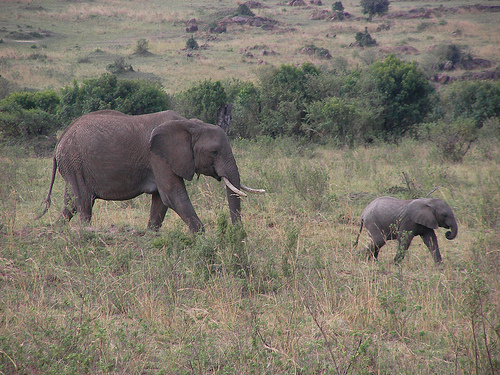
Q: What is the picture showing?
A: It is showing a field.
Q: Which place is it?
A: It is a field.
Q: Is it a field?
A: Yes, it is a field.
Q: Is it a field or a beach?
A: It is a field.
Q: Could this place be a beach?
A: No, it is a field.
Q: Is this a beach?
A: No, it is a field.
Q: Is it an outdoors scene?
A: Yes, it is outdoors.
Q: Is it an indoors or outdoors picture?
A: It is outdoors.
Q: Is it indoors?
A: No, it is outdoors.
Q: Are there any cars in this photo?
A: No, there are no cars.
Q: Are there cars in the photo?
A: No, there are no cars.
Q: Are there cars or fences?
A: No, there are no cars or fences.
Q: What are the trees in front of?
A: The trees are in front of the field.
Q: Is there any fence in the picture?
A: No, there are no fences.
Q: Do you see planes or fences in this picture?
A: No, there are no fences or planes.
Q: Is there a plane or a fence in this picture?
A: No, there are no fences or airplanes.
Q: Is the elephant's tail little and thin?
A: Yes, the tail is little and thin.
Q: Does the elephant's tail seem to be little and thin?
A: Yes, the tail is little and thin.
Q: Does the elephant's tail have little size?
A: Yes, the tail is little.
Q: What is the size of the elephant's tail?
A: The tail is little.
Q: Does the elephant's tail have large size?
A: No, the tail is little.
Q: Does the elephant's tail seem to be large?
A: No, the tail is little.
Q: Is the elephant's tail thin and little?
A: Yes, the tail is thin and little.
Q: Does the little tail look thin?
A: Yes, the tail is thin.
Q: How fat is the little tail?
A: The tail is thin.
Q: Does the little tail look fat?
A: No, the tail is thin.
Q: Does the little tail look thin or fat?
A: The tail is thin.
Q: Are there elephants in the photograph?
A: Yes, there is an elephant.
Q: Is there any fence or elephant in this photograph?
A: Yes, there is an elephant.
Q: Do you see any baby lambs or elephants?
A: Yes, there is a baby elephant.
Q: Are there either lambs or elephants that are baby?
A: Yes, the elephant is a baby.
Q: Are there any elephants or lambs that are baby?
A: Yes, the elephant is a baby.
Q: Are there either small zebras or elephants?
A: Yes, there is a small elephant.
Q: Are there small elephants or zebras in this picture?
A: Yes, there is a small elephant.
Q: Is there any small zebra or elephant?
A: Yes, there is a small elephant.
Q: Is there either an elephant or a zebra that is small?
A: Yes, the elephant is small.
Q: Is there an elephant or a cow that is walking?
A: Yes, the elephant is walking.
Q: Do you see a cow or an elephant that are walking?
A: Yes, the elephant is walking.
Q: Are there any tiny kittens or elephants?
A: Yes, there is a tiny elephant.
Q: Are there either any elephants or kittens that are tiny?
A: Yes, the elephant is tiny.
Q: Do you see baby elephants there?
A: Yes, there is a baby elephant.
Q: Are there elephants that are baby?
A: Yes, there is an elephant that is a baby.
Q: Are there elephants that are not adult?
A: Yes, there is an baby elephant.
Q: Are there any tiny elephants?
A: Yes, there is a tiny elephant.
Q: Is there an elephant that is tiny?
A: Yes, there is an elephant that is tiny.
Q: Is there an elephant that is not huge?
A: Yes, there is a tiny elephant.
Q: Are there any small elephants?
A: Yes, there is a small elephant.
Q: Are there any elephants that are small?
A: Yes, there is an elephant that is small.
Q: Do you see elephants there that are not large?
A: Yes, there is a small elephant.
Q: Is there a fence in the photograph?
A: No, there are no fences.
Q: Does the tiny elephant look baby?
A: Yes, the elephant is a baby.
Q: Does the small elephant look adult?
A: No, the elephant is a baby.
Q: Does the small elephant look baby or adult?
A: The elephant is a baby.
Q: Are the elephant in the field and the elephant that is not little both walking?
A: Yes, both the elephant and the elephant are walking.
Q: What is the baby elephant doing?
A: The elephant is walking.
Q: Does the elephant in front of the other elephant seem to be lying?
A: No, the elephant is walking.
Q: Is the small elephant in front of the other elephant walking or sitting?
A: The elephant is walking.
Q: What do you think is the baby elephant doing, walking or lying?
A: The elephant is walking.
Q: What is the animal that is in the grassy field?
A: The animal is an elephant.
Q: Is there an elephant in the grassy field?
A: Yes, there is an elephant in the field.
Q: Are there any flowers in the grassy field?
A: No, there is an elephant in the field.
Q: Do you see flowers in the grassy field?
A: No, there is an elephant in the field.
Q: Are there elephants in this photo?
A: Yes, there is an elephant.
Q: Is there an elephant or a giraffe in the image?
A: Yes, there is an elephant.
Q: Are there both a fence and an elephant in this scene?
A: No, there is an elephant but no fences.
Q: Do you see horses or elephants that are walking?
A: Yes, the elephant is walking.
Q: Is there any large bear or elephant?
A: Yes, there is a large elephant.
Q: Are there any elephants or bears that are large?
A: Yes, the elephant is large.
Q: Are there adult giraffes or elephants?
A: Yes, there is an adult elephant.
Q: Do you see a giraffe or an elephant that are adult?
A: Yes, the elephant is adult.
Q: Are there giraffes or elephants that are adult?
A: Yes, the elephant is adult.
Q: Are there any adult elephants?
A: Yes, there is an adult elephant.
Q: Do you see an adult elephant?
A: Yes, there is an adult elephant.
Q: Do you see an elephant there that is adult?
A: Yes, there is an elephant that is adult.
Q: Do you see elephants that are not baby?
A: Yes, there is a adult elephant.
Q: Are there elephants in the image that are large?
A: Yes, there is a large elephant.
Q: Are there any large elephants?
A: Yes, there is a large elephant.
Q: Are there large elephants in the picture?
A: Yes, there is a large elephant.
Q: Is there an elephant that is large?
A: Yes, there is an elephant that is large.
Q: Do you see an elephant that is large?
A: Yes, there is an elephant that is large.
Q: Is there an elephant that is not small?
A: Yes, there is a large elephant.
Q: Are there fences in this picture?
A: No, there are no fences.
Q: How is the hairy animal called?
A: The animal is an elephant.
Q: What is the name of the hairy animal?
A: The animal is an elephant.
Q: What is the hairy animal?
A: The animal is an elephant.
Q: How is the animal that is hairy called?
A: The animal is an elephant.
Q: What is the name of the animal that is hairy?
A: The animal is an elephant.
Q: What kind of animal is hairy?
A: The animal is an elephant.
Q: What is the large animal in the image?
A: The animal is an elephant.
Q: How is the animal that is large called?
A: The animal is an elephant.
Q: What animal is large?
A: The animal is an elephant.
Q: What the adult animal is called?
A: The animal is an elephant.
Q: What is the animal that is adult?
A: The animal is an elephant.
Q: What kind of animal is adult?
A: The animal is an elephant.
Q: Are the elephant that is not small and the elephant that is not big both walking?
A: Yes, both the elephant and the elephant are walking.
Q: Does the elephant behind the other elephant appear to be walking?
A: Yes, the elephant is walking.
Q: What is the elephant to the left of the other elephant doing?
A: The elephant is walking.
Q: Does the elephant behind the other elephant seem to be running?
A: No, the elephant is walking.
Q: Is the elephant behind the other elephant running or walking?
A: The elephant is walking.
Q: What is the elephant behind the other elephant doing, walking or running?
A: The elephant is walking.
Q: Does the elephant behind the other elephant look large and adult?
A: Yes, the elephant is large and adult.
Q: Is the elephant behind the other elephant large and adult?
A: Yes, the elephant is large and adult.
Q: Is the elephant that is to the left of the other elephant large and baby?
A: No, the elephant is large but adult.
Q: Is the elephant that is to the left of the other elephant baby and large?
A: No, the elephant is large but adult.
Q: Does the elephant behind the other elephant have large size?
A: Yes, the elephant is large.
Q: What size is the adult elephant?
A: The elephant is large.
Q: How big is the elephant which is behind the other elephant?
A: The elephant is large.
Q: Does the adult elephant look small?
A: No, the elephant is large.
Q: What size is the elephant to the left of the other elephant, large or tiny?
A: The elephant is large.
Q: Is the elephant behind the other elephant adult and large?
A: Yes, the elephant is adult and large.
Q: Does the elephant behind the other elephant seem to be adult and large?
A: Yes, the elephant is adult and large.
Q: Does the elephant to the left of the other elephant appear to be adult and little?
A: No, the elephant is adult but large.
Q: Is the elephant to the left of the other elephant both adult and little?
A: No, the elephant is adult but large.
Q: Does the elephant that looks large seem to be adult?
A: Yes, the elephant is adult.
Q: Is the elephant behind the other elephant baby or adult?
A: The elephant is adult.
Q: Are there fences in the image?
A: No, there are no fences.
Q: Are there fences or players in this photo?
A: No, there are no fences or players.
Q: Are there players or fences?
A: No, there are no fences or players.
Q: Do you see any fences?
A: No, there are no fences.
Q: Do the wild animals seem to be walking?
A: Yes, the animals are walking.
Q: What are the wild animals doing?
A: The animals are walking.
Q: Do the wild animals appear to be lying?
A: No, the animals are walking.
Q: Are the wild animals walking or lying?
A: The animals are walking.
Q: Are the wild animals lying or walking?
A: The animals are walking.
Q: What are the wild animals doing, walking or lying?
A: The animals are walking.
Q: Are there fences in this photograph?
A: No, there are no fences.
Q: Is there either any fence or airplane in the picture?
A: No, there are no fences or airplanes.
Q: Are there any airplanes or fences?
A: No, there are no fences or airplanes.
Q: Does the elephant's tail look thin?
A: Yes, the tail is thin.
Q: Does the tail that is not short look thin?
A: Yes, the tail is thin.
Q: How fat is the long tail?
A: The tail is thin.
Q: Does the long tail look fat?
A: No, the tail is thin.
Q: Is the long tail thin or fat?
A: The tail is thin.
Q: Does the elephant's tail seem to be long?
A: Yes, the tail is long.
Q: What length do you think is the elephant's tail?
A: The tail is long.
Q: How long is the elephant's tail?
A: The tail is long.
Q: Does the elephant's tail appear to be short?
A: No, the tail is long.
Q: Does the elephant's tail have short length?
A: No, the tail is long.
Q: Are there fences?
A: No, there are no fences.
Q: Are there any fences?
A: No, there are no fences.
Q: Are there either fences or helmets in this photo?
A: No, there are no fences or helmets.